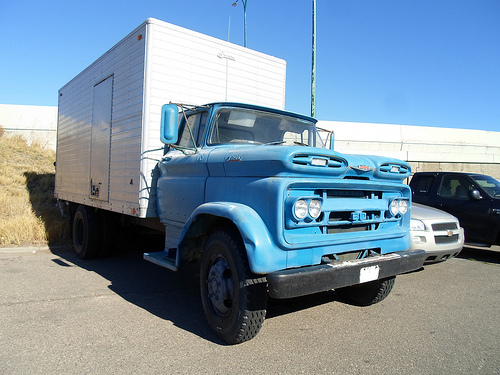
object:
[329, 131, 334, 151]
mirror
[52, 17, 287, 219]
trailer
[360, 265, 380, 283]
license plate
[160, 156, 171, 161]
handle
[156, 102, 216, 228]
door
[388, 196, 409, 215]
headlight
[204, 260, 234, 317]
hub cap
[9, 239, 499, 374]
parking lot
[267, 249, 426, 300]
bumpers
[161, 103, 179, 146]
mirror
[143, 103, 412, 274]
blue front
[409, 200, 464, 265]
car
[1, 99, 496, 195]
wall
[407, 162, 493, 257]
truck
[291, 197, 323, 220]
headlight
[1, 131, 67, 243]
grass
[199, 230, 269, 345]
tire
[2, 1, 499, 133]
sky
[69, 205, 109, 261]
rear wheels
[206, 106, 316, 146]
windshield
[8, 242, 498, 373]
road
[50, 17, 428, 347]
blue truck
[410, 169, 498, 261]
truck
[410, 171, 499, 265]
pickup truck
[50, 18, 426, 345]
truck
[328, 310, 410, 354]
lot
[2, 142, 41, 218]
patch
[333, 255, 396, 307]
tire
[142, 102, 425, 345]
front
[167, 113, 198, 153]
window